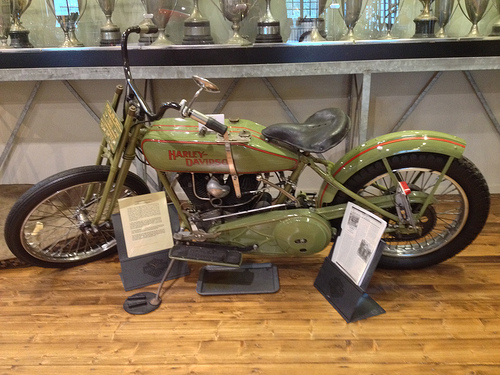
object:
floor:
[1, 185, 500, 375]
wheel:
[332, 152, 490, 270]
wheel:
[4, 165, 150, 267]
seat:
[262, 108, 351, 153]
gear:
[382, 202, 436, 241]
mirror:
[192, 75, 221, 94]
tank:
[142, 118, 307, 173]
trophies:
[0, 0, 35, 48]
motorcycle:
[5, 25, 489, 316]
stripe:
[140, 133, 300, 175]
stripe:
[319, 137, 463, 202]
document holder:
[108, 201, 189, 293]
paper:
[118, 191, 175, 257]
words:
[135, 209, 143, 215]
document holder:
[313, 223, 386, 323]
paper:
[331, 202, 387, 285]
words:
[347, 240, 355, 246]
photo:
[348, 212, 361, 228]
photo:
[357, 239, 375, 264]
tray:
[196, 264, 280, 296]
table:
[1, 36, 500, 193]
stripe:
[0, 39, 499, 68]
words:
[168, 149, 177, 161]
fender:
[318, 129, 464, 206]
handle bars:
[172, 103, 227, 135]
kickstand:
[151, 258, 176, 305]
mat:
[124, 292, 161, 314]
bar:
[0, 56, 499, 81]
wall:
[1, 69, 500, 194]